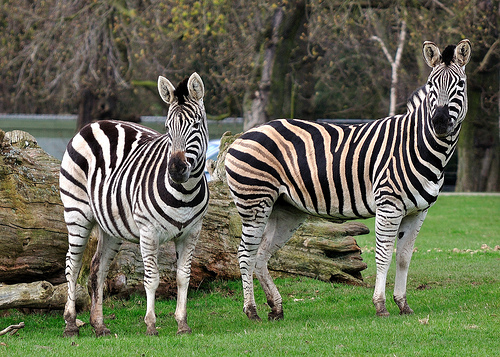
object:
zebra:
[59, 72, 209, 339]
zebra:
[224, 38, 473, 323]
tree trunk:
[0, 129, 368, 310]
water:
[1, 115, 61, 130]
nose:
[168, 158, 187, 175]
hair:
[174, 78, 189, 105]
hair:
[442, 45, 456, 67]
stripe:
[268, 117, 321, 213]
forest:
[5, 1, 499, 193]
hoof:
[145, 322, 158, 336]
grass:
[0, 193, 499, 356]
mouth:
[169, 173, 190, 183]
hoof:
[177, 319, 192, 334]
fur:
[441, 62, 450, 90]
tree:
[232, 3, 316, 125]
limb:
[140, 230, 160, 324]